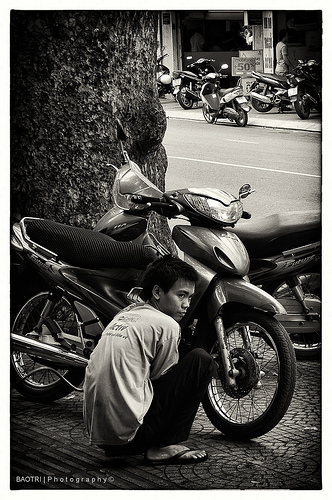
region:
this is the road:
[196, 141, 230, 157]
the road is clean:
[210, 130, 257, 152]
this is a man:
[87, 249, 214, 462]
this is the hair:
[163, 265, 172, 269]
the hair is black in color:
[158, 259, 175, 270]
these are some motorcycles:
[17, 147, 314, 491]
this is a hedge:
[29, 8, 138, 122]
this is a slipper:
[149, 444, 207, 460]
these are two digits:
[236, 59, 251, 68]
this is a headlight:
[185, 187, 241, 223]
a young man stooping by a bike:
[19, 191, 277, 442]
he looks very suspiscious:
[83, 267, 246, 466]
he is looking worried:
[77, 262, 304, 464]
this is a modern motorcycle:
[25, 189, 295, 441]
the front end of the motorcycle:
[107, 160, 261, 275]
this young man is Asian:
[136, 252, 210, 325]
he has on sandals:
[147, 441, 218, 475]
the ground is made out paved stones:
[42, 439, 309, 484]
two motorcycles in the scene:
[35, 152, 308, 258]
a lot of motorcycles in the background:
[163, 43, 318, 142]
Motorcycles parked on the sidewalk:
[9, 117, 319, 437]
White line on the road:
[166, 154, 320, 177]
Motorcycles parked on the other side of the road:
[155, 31, 321, 124]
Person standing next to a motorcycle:
[273, 29, 292, 75]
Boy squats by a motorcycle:
[81, 249, 206, 461]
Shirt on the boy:
[81, 302, 179, 444]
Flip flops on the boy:
[146, 444, 209, 463]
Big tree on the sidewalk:
[13, 10, 179, 289]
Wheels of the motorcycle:
[9, 287, 295, 437]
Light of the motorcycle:
[183, 193, 244, 225]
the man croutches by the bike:
[77, 251, 223, 471]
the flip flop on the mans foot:
[140, 442, 214, 464]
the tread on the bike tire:
[274, 330, 298, 417]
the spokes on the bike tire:
[232, 328, 262, 420]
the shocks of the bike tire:
[213, 316, 247, 389]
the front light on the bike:
[185, 187, 246, 228]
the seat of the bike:
[17, 214, 145, 274]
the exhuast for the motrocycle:
[10, 326, 83, 367]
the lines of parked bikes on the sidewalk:
[153, 49, 326, 128]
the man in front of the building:
[265, 30, 296, 80]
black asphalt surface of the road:
[177, 122, 199, 147]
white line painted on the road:
[215, 155, 275, 177]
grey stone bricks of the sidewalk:
[233, 454, 317, 483]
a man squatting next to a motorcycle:
[67, 258, 219, 475]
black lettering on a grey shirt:
[99, 307, 144, 344]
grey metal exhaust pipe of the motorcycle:
[4, 325, 86, 372]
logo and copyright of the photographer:
[12, 468, 124, 488]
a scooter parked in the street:
[198, 84, 250, 126]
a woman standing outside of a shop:
[269, 28, 294, 80]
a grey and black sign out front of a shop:
[230, 54, 256, 79]